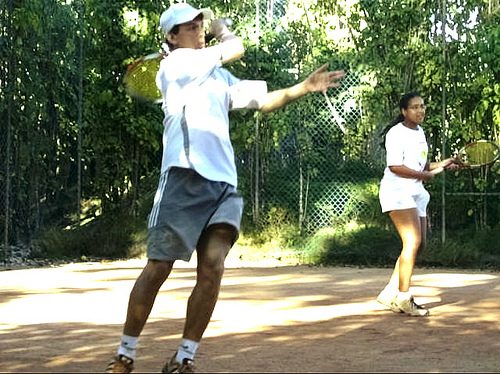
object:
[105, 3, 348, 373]
person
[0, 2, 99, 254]
tree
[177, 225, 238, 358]
leg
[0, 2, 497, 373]
tennis court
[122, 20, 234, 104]
tennis racket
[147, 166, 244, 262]
pants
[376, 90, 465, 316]
girl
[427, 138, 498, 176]
racket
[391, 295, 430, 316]
sneaker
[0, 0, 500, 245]
fence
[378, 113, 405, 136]
braid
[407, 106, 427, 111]
glasses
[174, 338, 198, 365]
socks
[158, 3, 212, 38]
cap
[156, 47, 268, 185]
shirt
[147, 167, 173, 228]
stripe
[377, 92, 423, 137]
hair